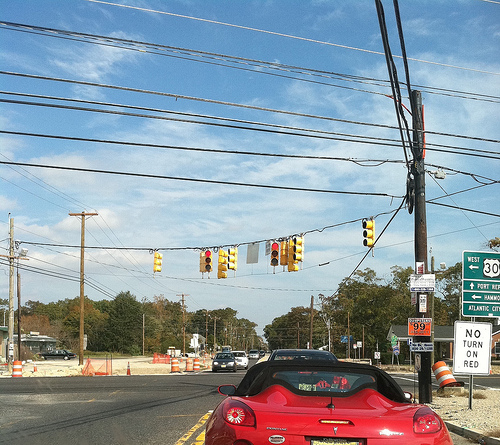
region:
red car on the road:
[184, 355, 454, 442]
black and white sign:
[449, 318, 499, 379]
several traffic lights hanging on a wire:
[128, 208, 385, 289]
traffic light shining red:
[198, 247, 219, 275]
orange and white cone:
[11, 359, 26, 377]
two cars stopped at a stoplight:
[205, 337, 253, 379]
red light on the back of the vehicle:
[219, 399, 254, 431]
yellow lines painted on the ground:
[161, 404, 223, 444]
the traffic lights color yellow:
[139, 213, 390, 284]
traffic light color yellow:
[357, 213, 379, 250]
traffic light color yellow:
[149, 244, 165, 274]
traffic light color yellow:
[201, 242, 213, 275]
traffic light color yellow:
[266, 234, 282, 272]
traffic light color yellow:
[287, 230, 310, 262]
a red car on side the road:
[198, 353, 454, 443]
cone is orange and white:
[166, 352, 186, 375]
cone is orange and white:
[8, 356, 25, 378]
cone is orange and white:
[188, 354, 205, 372]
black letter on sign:
[461, 325, 473, 337]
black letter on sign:
[473, 327, 482, 338]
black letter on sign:
[462, 336, 468, 346]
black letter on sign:
[466, 340, 472, 347]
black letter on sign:
[471, 337, 478, 348]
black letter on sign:
[476, 339, 485, 348]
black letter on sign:
[463, 347, 473, 359]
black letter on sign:
[470, 347, 480, 359]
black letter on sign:
[461, 356, 468, 368]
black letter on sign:
[472, 357, 479, 368]